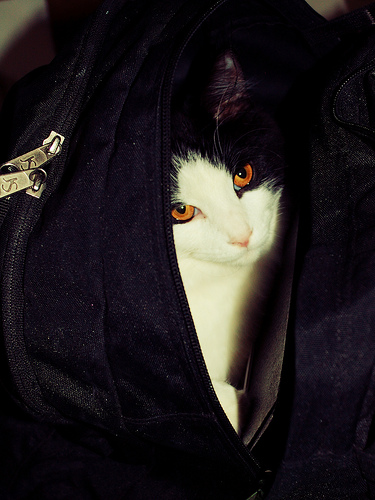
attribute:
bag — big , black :
[0, 0, 373, 498]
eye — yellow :
[168, 201, 197, 223]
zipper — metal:
[9, 120, 111, 238]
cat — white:
[142, 136, 331, 320]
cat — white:
[152, 52, 297, 327]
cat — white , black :
[158, 47, 297, 461]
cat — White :
[163, 44, 297, 389]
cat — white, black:
[165, 51, 288, 437]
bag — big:
[33, 93, 166, 410]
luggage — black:
[1, 0, 373, 497]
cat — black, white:
[159, 125, 285, 430]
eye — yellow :
[231, 161, 259, 191]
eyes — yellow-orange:
[155, 119, 272, 225]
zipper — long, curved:
[0, 67, 95, 392]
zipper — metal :
[4, 127, 65, 199]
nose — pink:
[226, 226, 252, 249]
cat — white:
[155, 124, 307, 324]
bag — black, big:
[32, 28, 372, 313]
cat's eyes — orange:
[169, 157, 252, 223]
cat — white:
[174, 46, 302, 414]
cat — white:
[156, 120, 293, 367]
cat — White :
[164, 116, 303, 283]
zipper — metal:
[5, 170, 53, 197]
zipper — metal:
[6, 131, 78, 167]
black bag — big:
[1, 5, 373, 498]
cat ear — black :
[208, 44, 253, 119]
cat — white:
[152, 57, 302, 442]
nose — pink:
[216, 220, 262, 255]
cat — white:
[114, 46, 315, 268]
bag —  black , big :
[9, 43, 373, 494]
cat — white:
[162, 46, 280, 434]